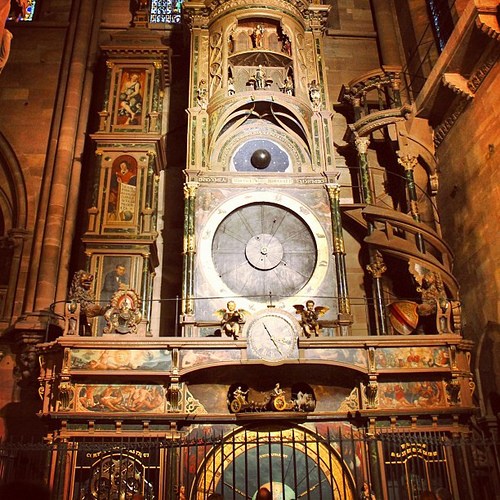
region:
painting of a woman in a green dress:
[112, 55, 147, 126]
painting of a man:
[97, 153, 138, 230]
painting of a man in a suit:
[103, 259, 130, 294]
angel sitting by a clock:
[289, 289, 336, 333]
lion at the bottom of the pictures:
[59, 263, 111, 322]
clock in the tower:
[246, 310, 298, 357]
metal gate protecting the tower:
[7, 428, 484, 498]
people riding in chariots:
[217, 377, 317, 417]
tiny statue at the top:
[246, 19, 265, 56]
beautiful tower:
[83, 23, 445, 385]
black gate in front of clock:
[8, 425, 498, 498]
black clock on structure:
[200, 194, 328, 309]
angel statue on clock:
[290, 294, 334, 339]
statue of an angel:
[215, 295, 245, 338]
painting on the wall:
[101, 254, 135, 292]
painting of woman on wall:
[117, 67, 150, 129]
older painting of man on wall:
[107, 149, 143, 224]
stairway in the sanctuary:
[357, 203, 469, 285]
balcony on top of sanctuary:
[402, 0, 478, 93]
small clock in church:
[243, 310, 300, 368]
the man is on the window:
[111, 263, 133, 293]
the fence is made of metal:
[0, 435, 490, 499]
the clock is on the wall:
[247, 320, 296, 354]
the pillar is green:
[183, 197, 195, 237]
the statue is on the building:
[221, 307, 246, 338]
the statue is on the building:
[296, 302, 331, 334]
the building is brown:
[1, 0, 79, 306]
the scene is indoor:
[6, 10, 494, 497]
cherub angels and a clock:
[208, 291, 340, 370]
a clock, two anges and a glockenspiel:
[179, 172, 351, 431]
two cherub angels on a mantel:
[207, 289, 357, 367]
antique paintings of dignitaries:
[72, 53, 177, 350]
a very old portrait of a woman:
[105, 60, 153, 135]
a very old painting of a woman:
[95, 54, 168, 141]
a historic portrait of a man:
[93, 149, 148, 238]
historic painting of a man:
[89, 147, 153, 239]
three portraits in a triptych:
[84, 37, 169, 349]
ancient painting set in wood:
[60, 377, 177, 413]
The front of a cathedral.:
[46, 58, 470, 467]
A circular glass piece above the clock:
[211, 203, 323, 298]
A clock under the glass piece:
[251, 313, 298, 362]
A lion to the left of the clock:
[67, 262, 107, 332]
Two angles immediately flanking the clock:
[223, 302, 327, 337]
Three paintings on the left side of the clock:
[102, 61, 146, 328]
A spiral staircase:
[356, 73, 447, 325]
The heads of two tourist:
[204, 480, 286, 498]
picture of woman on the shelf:
[93, 46, 171, 138]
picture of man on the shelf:
[92, 244, 147, 339]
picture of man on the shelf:
[88, 139, 162, 236]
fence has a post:
[220, 431, 223, 496]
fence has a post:
[241, 434, 249, 497]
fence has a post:
[254, 429, 262, 498]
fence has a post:
[269, 431, 273, 498]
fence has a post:
[278, 434, 288, 498]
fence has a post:
[290, 431, 299, 497]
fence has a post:
[304, 431, 311, 496]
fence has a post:
[314, 429, 324, 497]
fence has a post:
[326, 431, 333, 498]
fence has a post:
[339, 426, 343, 496]